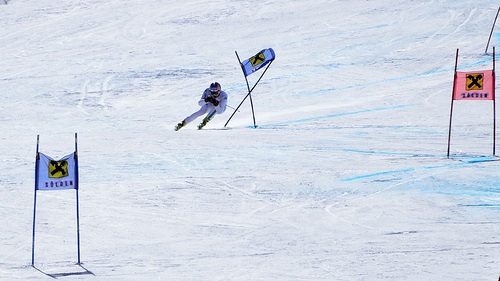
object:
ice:
[79, 172, 329, 234]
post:
[224, 47, 276, 126]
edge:
[235, 51, 241, 58]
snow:
[277, 3, 499, 109]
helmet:
[209, 82, 221, 96]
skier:
[175, 82, 228, 132]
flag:
[241, 47, 276, 77]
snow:
[144, 6, 286, 138]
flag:
[453, 69, 496, 100]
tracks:
[423, 6, 478, 43]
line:
[295, 56, 494, 96]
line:
[258, 102, 422, 131]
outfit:
[182, 88, 228, 125]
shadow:
[203, 128, 230, 130]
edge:
[73, 150, 78, 188]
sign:
[34, 151, 79, 191]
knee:
[198, 110, 207, 114]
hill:
[1, 1, 498, 280]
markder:
[222, 48, 277, 128]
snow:
[2, 4, 162, 268]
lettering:
[44, 180, 73, 187]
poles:
[234, 51, 257, 128]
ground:
[0, 0, 496, 280]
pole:
[446, 48, 459, 159]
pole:
[492, 46, 496, 157]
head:
[209, 82, 221, 94]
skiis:
[174, 122, 187, 131]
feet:
[175, 122, 188, 131]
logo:
[249, 51, 266, 66]